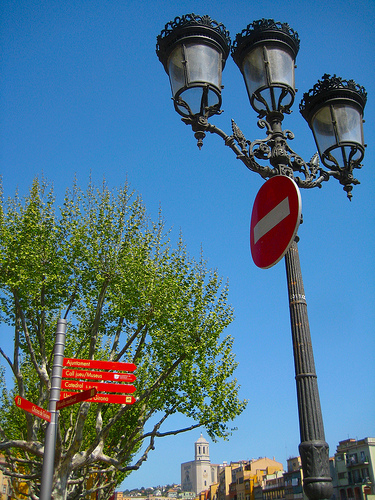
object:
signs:
[13, 393, 52, 423]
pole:
[40, 316, 64, 499]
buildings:
[181, 432, 219, 497]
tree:
[0, 164, 250, 500]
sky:
[0, 0, 375, 492]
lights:
[155, 13, 233, 118]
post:
[271, 161, 334, 498]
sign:
[248, 171, 302, 270]